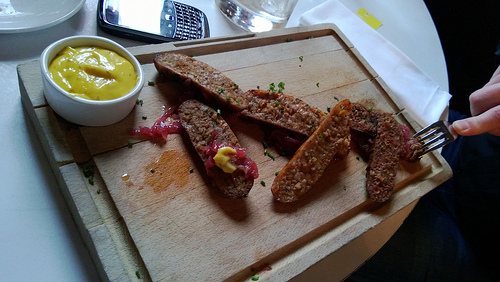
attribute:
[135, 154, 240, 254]
board — wood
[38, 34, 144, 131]
bowl — white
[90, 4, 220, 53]
phone — black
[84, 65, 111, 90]
mustard — bright yellow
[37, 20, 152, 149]
bowl — round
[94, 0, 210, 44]
cellphone — shiny, black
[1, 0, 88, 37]
round/ceramic/white plate — ceramic, white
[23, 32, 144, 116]
bowl — small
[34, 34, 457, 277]
cutting board — rectangular, wood, light brown, wooden, brown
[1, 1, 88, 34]
plate — round, white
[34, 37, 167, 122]
dish — white, round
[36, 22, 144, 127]
white dish — small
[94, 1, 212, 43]
blackberry — black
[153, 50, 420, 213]
sausage — sliced, cooked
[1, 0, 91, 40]
plate — round